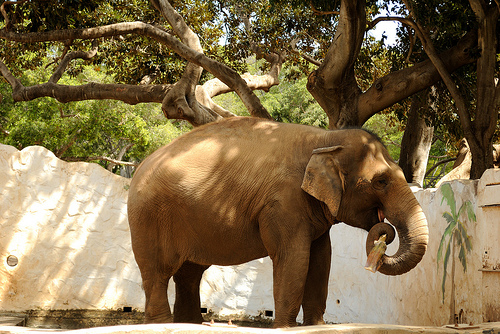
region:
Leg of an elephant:
[119, 191, 186, 321]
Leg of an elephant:
[252, 208, 309, 325]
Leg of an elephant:
[308, 211, 339, 326]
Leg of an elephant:
[170, 236, 205, 321]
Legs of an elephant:
[127, 233, 341, 329]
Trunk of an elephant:
[354, 139, 441, 290]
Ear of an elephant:
[289, 127, 363, 229]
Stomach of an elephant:
[144, 127, 259, 259]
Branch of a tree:
[56, 25, 278, 115]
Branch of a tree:
[329, 7, 368, 122]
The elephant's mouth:
[373, 203, 385, 220]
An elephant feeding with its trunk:
[125, 116, 430, 331]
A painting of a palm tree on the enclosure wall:
[431, 180, 481, 330]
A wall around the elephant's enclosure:
[0, 140, 497, 331]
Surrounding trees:
[0, 0, 498, 207]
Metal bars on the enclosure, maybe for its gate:
[477, 173, 498, 330]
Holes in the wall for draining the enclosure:
[108, 300, 304, 331]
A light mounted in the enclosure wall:
[6, 250, 20, 271]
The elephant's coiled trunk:
[362, 163, 429, 277]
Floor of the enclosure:
[0, 305, 368, 330]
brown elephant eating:
[128, 109, 430, 332]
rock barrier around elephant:
[4, 147, 121, 307]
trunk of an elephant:
[366, 190, 428, 272]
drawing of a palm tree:
[431, 180, 479, 325]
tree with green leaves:
[14, 107, 119, 146]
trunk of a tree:
[320, 6, 359, 116]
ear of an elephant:
[301, 143, 351, 217]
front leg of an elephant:
[259, 193, 310, 324]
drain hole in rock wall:
[260, 306, 275, 320]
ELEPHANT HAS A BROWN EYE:
[374, 176, 386, 186]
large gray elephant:
[100, 98, 428, 326]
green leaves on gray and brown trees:
[16, 19, 82, 78]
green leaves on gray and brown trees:
[23, 83, 91, 123]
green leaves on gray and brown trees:
[76, 99, 143, 139]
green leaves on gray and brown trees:
[77, 42, 208, 134]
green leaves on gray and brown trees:
[162, 18, 252, 66]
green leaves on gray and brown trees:
[265, 16, 352, 67]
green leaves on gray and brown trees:
[240, 50, 315, 95]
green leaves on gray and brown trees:
[355, 5, 442, 64]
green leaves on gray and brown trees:
[387, 69, 474, 131]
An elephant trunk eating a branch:
[355, 206, 427, 282]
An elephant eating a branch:
[100, 98, 447, 329]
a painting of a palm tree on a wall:
[423, 173, 480, 315]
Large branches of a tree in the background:
[11, 3, 448, 95]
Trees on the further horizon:
[0, 112, 162, 172]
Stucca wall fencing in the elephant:
[1, 120, 129, 325]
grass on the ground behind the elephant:
[14, 301, 66, 331]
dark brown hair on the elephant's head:
[287, 115, 399, 147]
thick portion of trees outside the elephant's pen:
[404, 1, 495, 178]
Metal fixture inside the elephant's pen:
[436, 291, 483, 331]